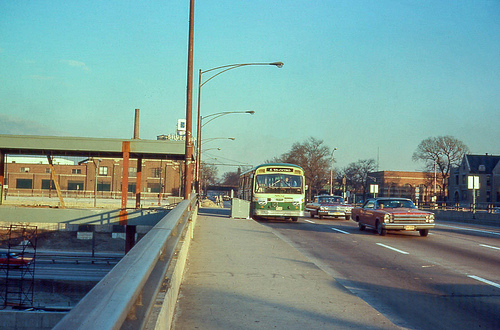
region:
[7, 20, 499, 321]
picture taken on a city street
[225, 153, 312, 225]
bus stopped on street at bus stop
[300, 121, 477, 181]
trees with no leaves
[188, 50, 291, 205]
street lights over hanging the street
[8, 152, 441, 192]
red brick buildings on both sides of street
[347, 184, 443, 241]
old fashioned red car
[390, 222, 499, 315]
white lines painted on street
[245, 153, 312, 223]
bus painted green and white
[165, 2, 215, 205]
tall brown utility pole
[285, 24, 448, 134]
clear blue sky with no clouds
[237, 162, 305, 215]
old green and yellow bus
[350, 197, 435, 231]
red car with chrome bumper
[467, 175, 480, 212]
backside of metal street sign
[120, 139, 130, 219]
rusty metal beam holding up roof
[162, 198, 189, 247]
metal safety railing on side of bridge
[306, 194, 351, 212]
red car beside green and yellow bus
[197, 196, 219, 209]
construction area on sidewalk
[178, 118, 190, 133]
blue and white sign on rusty metal pole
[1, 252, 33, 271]
red car driving under bridge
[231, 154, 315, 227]
Green bus on the road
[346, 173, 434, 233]
red car on the road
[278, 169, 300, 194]
operator driving the bus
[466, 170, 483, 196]
sign on a pole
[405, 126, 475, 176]
tree with no leaves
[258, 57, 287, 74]
light on a lamp post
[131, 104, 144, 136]
smoke stack on a building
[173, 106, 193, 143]
electric box on a building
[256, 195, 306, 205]
head lights on a bus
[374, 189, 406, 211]
two people in a car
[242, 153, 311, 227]
autobus on the street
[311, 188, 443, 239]
vehicles on the street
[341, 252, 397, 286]
lane of a street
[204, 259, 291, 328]
sidewalk of a street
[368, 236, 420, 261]
white marks on a street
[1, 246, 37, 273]
vehicle on street below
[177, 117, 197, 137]
banner hanging off pole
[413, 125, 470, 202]
tree with few leaves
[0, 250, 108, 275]
street beneath street above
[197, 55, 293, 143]
lights on the street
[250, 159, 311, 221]
bus on the road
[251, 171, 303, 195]
windshield on the bus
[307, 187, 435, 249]
cars driving down the road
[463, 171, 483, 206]
back of a road sign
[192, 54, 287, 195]
light poles on the side of the road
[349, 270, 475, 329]
shadow on the road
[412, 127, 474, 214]
tree growing on the sidewalk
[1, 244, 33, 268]
car on the road below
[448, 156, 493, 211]
buildings across the road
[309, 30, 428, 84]
sky is a clear blue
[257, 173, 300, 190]
a window on a bus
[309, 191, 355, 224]
a car on a street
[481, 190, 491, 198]
a window on a building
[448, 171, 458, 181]
a window on a building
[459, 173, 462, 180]
a window on a building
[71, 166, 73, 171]
a window on a building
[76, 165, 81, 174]
a window on a building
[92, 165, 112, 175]
a window on a building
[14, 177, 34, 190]
glass window on building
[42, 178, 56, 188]
glass window on building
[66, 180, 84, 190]
glass window on building